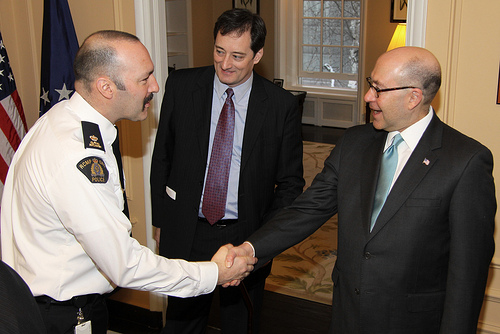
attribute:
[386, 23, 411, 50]
lamp — in background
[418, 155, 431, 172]
pin — american, flag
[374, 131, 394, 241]
tie — light, blue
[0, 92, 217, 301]
shirt — white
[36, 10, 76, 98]
flag — red, white,  blue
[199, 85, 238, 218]
tie — man's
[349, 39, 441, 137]
man — is smiling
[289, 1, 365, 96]
window — paneled, open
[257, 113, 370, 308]
rug — patterned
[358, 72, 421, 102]
glasses — black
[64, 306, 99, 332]
name tag — white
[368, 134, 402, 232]
blue tie —  blue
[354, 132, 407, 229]
tie — blue, silky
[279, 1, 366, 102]
open window — Open 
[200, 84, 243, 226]
tie — red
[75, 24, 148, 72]
baldness — Typical, male, pattern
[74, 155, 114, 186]
patch — black,  gold 